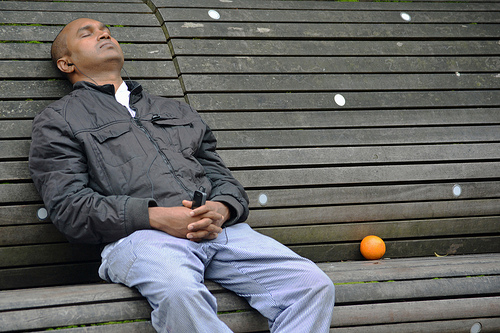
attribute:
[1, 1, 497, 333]
bench — wooden, weathered, wood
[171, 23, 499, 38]
slat — wooden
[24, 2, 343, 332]
man — clean shaven, resting, lisitening, sleeping, relaxing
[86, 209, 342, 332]
jeans — light blue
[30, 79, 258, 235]
jacket — warm, gray, grey, black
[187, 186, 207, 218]
mp3 player — phone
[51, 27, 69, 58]
hair — short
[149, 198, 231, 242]
skin — dark, crossed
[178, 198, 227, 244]
fingers — interlaced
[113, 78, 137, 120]
shirt — white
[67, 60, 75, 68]
earbud — black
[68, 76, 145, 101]
collar — upturned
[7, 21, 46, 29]
vegetation — green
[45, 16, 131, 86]
skin — dark